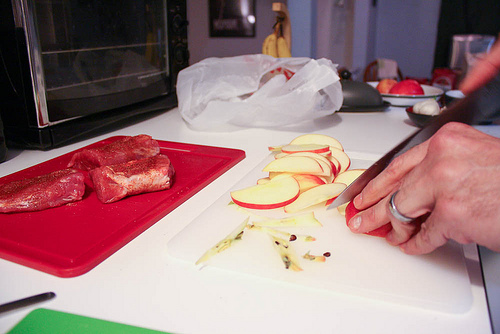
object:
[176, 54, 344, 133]
bag counter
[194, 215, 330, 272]
apple seeds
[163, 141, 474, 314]
cutting board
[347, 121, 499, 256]
hand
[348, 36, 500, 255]
person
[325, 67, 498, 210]
knife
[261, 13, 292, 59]
bananas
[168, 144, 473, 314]
board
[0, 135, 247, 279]
cutting board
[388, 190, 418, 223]
ring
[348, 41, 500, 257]
man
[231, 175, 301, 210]
apple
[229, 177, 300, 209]
slice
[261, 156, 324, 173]
slice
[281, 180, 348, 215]
slice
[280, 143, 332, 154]
slice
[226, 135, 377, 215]
apples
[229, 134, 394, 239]
apple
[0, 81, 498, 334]
counter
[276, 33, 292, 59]
banana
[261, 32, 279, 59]
banana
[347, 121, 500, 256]
person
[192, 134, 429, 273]
apple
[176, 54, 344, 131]
bag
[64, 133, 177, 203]
meat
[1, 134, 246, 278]
red tray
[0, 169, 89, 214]
meat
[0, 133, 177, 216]
meat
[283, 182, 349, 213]
apple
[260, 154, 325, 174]
apple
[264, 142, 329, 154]
apple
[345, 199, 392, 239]
apple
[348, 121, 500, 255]
left hand